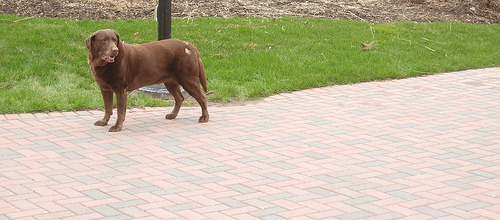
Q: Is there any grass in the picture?
A: Yes, there is grass.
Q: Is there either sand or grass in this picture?
A: Yes, there is grass.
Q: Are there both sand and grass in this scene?
A: No, there is grass but no sand.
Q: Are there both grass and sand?
A: No, there is grass but no sand.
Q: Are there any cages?
A: No, there are no cages.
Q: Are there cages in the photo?
A: No, there are no cages.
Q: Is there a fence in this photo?
A: No, there are no fences.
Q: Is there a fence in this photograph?
A: No, there are no fences.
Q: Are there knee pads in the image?
A: No, there are no knee pads.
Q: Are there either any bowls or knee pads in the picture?
A: No, there are no knee pads or bowls.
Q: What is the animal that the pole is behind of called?
A: The animal is a dog.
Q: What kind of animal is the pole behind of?
A: The pole is behind the dog.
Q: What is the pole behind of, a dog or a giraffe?
A: The pole is behind a dog.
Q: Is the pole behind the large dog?
A: Yes, the pole is behind the dog.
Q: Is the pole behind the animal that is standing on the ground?
A: Yes, the pole is behind the dog.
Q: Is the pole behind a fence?
A: No, the pole is behind the dog.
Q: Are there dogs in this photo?
A: Yes, there is a dog.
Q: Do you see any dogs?
A: Yes, there is a dog.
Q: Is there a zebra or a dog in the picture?
A: Yes, there is a dog.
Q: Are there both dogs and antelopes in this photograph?
A: No, there is a dog but no antelopes.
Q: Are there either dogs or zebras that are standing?
A: Yes, the dog is standing.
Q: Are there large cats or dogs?
A: Yes, there is a large dog.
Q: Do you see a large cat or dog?
A: Yes, there is a large dog.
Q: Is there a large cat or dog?
A: Yes, there is a large dog.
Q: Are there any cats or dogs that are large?
A: Yes, the dog is large.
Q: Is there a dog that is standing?
A: Yes, there is a dog that is standing.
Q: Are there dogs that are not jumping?
A: Yes, there is a dog that is standing.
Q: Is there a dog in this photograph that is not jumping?
A: Yes, there is a dog that is standing.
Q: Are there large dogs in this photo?
A: Yes, there is a large dog.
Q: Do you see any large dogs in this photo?
A: Yes, there is a large dog.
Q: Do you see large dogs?
A: Yes, there is a large dog.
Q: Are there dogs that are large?
A: Yes, there is a dog that is large.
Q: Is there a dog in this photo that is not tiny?
A: Yes, there is a large dog.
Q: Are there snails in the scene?
A: No, there are no snails.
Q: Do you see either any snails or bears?
A: No, there are no snails or bears.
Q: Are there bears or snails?
A: No, there are no snails or bears.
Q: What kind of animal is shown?
A: The animal is a dog.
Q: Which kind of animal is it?
A: The animal is a dog.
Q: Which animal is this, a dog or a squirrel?
A: That is a dog.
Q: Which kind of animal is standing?
A: The animal is a dog.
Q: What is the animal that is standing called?
A: The animal is a dog.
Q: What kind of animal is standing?
A: The animal is a dog.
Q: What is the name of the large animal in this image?
A: The animal is a dog.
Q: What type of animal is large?
A: The animal is a dog.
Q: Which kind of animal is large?
A: The animal is a dog.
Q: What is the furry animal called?
A: The animal is a dog.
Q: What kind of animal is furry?
A: The animal is a dog.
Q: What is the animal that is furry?
A: The animal is a dog.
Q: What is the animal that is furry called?
A: The animal is a dog.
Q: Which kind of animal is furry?
A: The animal is a dog.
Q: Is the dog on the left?
A: Yes, the dog is on the left of the image.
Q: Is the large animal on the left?
A: Yes, the dog is on the left of the image.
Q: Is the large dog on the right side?
A: No, the dog is on the left of the image.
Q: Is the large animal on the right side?
A: No, the dog is on the left of the image.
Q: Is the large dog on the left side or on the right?
A: The dog is on the left of the image.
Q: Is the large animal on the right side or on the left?
A: The dog is on the left of the image.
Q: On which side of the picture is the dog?
A: The dog is on the left of the image.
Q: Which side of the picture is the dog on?
A: The dog is on the left of the image.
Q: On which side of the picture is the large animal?
A: The dog is on the left of the image.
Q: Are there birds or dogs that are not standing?
A: No, there is a dog but it is standing.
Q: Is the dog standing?
A: Yes, the dog is standing.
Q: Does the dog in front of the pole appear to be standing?
A: Yes, the dog is standing.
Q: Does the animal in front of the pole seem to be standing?
A: Yes, the dog is standing.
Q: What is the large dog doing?
A: The dog is standing.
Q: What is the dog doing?
A: The dog is standing.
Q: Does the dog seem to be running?
A: No, the dog is standing.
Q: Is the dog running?
A: No, the dog is standing.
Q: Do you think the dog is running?
A: No, the dog is standing.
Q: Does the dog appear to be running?
A: No, the dog is standing.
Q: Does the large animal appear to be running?
A: No, the dog is standing.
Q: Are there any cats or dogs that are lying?
A: No, there is a dog but it is standing.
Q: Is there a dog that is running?
A: No, there is a dog but it is standing.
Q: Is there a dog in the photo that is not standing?
A: No, there is a dog but it is standing.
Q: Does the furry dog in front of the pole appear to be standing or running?
A: The dog is standing.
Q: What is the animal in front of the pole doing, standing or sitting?
A: The dog is standing.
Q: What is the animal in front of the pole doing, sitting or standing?
A: The dog is standing.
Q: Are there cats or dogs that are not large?
A: No, there is a dog but it is large.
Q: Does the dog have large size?
A: Yes, the dog is large.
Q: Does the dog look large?
A: Yes, the dog is large.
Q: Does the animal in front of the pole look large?
A: Yes, the dog is large.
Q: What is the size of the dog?
A: The dog is large.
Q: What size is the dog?
A: The dog is large.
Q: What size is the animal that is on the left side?
A: The dog is large.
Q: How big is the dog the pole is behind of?
A: The dog is large.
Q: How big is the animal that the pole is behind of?
A: The dog is large.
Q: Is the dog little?
A: No, the dog is large.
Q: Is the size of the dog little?
A: No, the dog is large.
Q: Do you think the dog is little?
A: No, the dog is large.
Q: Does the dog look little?
A: No, the dog is large.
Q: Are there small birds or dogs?
A: No, there is a dog but it is large.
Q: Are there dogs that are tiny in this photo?
A: No, there is a dog but it is large.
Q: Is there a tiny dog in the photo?
A: No, there is a dog but it is large.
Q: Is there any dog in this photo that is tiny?
A: No, there is a dog but it is large.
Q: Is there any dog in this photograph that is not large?
A: No, there is a dog but it is large.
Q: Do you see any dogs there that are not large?
A: No, there is a dog but it is large.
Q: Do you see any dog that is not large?
A: No, there is a dog but it is large.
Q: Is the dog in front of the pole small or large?
A: The dog is large.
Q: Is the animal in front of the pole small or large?
A: The dog is large.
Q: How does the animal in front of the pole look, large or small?
A: The dog is large.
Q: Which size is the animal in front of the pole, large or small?
A: The dog is large.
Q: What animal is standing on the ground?
A: The dog is standing on the ground.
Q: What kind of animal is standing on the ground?
A: The animal is a dog.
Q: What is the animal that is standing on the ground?
A: The animal is a dog.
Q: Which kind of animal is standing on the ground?
A: The animal is a dog.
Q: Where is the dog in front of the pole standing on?
A: The dog is standing on the ground.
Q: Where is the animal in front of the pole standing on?
A: The dog is standing on the ground.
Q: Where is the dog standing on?
A: The dog is standing on the ground.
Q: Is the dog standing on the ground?
A: Yes, the dog is standing on the ground.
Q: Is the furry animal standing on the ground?
A: Yes, the dog is standing on the ground.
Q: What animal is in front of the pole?
A: The dog is in front of the pole.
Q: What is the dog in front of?
A: The dog is in front of the pole.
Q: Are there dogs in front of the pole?
A: Yes, there is a dog in front of the pole.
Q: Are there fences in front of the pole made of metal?
A: No, there is a dog in front of the pole.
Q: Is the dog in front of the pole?
A: Yes, the dog is in front of the pole.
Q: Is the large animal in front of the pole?
A: Yes, the dog is in front of the pole.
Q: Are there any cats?
A: No, there are no cats.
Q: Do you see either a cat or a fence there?
A: No, there are no cats or fences.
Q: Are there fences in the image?
A: No, there are no fences.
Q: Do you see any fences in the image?
A: No, there are no fences.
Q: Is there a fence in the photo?
A: No, there are no fences.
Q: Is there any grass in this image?
A: Yes, there is grass.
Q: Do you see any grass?
A: Yes, there is grass.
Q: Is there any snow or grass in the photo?
A: Yes, there is grass.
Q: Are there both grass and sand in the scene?
A: No, there is grass but no sand.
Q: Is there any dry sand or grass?
A: Yes, there is dry grass.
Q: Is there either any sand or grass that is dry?
A: Yes, the grass is dry.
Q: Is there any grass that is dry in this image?
A: Yes, there is dry grass.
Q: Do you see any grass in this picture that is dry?
A: Yes, there is grass that is dry.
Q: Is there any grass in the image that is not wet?
A: Yes, there is dry grass.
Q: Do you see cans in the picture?
A: No, there are no cans.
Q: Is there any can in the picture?
A: No, there are no cans.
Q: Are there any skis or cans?
A: No, there are no cans or skis.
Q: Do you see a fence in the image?
A: No, there are no fences.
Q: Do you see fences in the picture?
A: No, there are no fences.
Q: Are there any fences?
A: No, there are no fences.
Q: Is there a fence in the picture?
A: No, there are no fences.